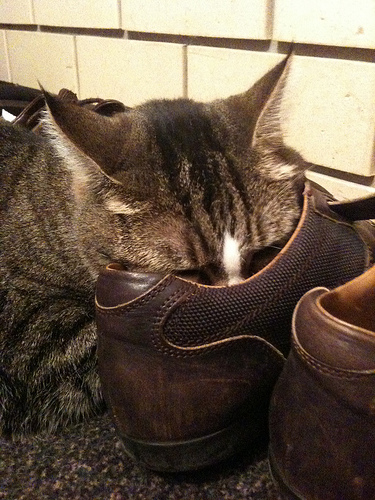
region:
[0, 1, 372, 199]
tile wall behind cat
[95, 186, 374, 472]
cat sniffing a brown shoe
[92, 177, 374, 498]
two shoes are side by side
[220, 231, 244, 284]
the cat has a white mark above his nose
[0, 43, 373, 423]
the cat is a tabby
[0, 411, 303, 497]
the cat sits on a brown rug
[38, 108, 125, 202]
hairs inside cats ear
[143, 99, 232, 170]
dark stripe on the top of cats head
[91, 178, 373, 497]
shoes are leather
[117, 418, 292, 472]
sole of the shoe is black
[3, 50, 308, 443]
Cat with face on shoe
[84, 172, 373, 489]
Two brown shoes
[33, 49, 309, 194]
Hairy pointy ears of cat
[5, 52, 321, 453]
Cat is color tan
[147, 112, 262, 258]
Cat has black stripes on front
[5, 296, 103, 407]
Black stripes on the arm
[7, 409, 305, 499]
Carpet is brown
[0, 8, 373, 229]
Wall is tiled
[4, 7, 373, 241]
Wall is black and white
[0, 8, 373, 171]
Tiles are white and reactangular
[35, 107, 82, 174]
fluffy white ear fur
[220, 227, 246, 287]
a white streak of fur between the cat's eyes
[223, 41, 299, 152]
an ear of the cat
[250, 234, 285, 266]
an eye of the cat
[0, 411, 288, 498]
gray carpet in front of the cat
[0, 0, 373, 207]
a wall made of white blocks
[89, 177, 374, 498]
a pair of brown shoes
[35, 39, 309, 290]
cat's head in a shoe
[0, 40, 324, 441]
a cat on the carpet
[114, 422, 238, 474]
the black sole of a shoe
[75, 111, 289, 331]
cat's face in a shoe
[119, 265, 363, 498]
the shoes is brown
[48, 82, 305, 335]
the cat is stripes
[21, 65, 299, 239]
the cat has two ears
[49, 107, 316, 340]
the cat is sleeping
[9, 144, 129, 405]
the cat's color is brown and black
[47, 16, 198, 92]
the wall is tiled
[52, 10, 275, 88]
the wall is white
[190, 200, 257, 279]
there is white mark in cat's face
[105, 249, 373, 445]
the shoes is leather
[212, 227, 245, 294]
cat's nose sniffing shoe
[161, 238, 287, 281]
cat's sleepy eyes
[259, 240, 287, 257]
cat's eyebrow whisker folded by shoe's collar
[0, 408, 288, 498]
scrubbly dark brown carpet with other, lighter earth tone yarns mixed in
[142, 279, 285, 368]
man's brown shoe has double seams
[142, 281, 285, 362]
shoes seam is reverse question mark shaped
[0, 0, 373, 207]
room wherein cat sniffs in, & snoozes upon, shoe, is tiled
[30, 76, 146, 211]
cat's ear fur fuzz in shades of brown from almost white to almost black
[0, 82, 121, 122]
top of another shoes is behind sniffing cat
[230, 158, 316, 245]
cat's eye whisker points upward & to cat's left